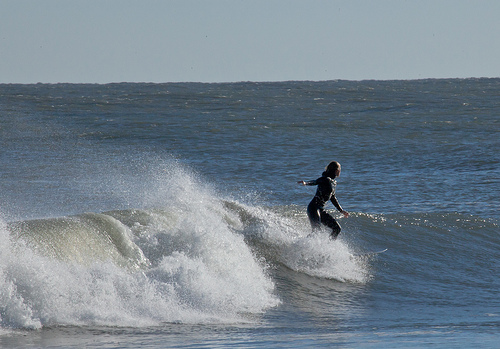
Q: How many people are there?
A: 1.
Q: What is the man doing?
A: Wakeboarding.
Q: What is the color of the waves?
A: White.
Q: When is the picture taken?
A: Daytime.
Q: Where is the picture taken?
A: At the ocean.